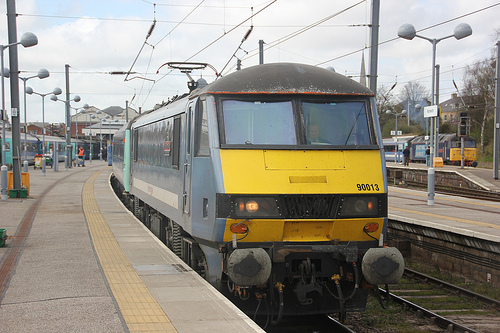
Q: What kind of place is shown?
A: It is a station.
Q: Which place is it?
A: It is a station.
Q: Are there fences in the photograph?
A: No, there are no fences.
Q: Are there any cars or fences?
A: No, there are no fences or cars.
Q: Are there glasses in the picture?
A: No, there are no glasses.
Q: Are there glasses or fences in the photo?
A: No, there are no glasses or fences.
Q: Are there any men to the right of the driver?
A: Yes, there is a man to the right of the driver.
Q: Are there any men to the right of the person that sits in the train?
A: Yes, there is a man to the right of the driver.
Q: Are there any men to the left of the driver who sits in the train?
A: No, the man is to the right of the driver.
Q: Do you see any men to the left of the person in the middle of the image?
A: No, the man is to the right of the driver.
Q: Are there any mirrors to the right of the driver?
A: No, there is a man to the right of the driver.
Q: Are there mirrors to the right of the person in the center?
A: No, there is a man to the right of the driver.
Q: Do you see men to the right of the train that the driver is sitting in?
A: Yes, there is a man to the right of the train.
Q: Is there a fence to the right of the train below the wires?
A: No, there is a man to the right of the train.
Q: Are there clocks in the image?
A: No, there are no clocks.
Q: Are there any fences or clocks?
A: No, there are no clocks or fences.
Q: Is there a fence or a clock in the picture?
A: No, there are no clocks or fences.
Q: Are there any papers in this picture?
A: No, there are no papers.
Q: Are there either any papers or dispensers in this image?
A: No, there are no papers or dispensers.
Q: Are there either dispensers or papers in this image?
A: No, there are no papers or dispensers.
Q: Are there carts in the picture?
A: No, there are no carts.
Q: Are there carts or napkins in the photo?
A: No, there are no carts or napkins.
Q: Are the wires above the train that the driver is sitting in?
A: Yes, the wires are above the train.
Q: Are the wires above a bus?
A: No, the wires are above the train.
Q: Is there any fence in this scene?
A: No, there are no fences.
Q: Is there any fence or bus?
A: No, there are no fences or buses.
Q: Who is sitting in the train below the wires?
A: The driver is sitting in the train.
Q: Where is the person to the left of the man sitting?
A: The driver is sitting in the train.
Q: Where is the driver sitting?
A: The driver is sitting in the train.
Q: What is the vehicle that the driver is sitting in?
A: The vehicle is a train.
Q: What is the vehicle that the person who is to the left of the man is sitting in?
A: The vehicle is a train.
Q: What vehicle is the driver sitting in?
A: The driver is sitting in the train.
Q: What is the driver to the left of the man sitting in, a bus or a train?
A: The driver is sitting in a train.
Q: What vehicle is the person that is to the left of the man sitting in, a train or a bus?
A: The driver is sitting in a train.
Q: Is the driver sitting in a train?
A: Yes, the driver is sitting in a train.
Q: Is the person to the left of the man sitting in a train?
A: Yes, the driver is sitting in a train.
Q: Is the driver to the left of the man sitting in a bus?
A: No, the driver is sitting in a train.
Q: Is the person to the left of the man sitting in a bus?
A: No, the driver is sitting in a train.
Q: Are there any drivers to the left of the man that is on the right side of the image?
A: Yes, there is a driver to the left of the man.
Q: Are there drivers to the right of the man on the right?
A: No, the driver is to the left of the man.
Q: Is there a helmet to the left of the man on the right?
A: No, there is a driver to the left of the man.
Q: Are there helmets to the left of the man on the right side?
A: No, there is a driver to the left of the man.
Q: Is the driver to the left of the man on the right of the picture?
A: Yes, the driver is to the left of the man.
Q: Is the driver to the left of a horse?
A: No, the driver is to the left of the man.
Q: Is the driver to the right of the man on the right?
A: No, the driver is to the left of the man.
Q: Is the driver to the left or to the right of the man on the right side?
A: The driver is to the left of the man.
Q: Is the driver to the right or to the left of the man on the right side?
A: The driver is to the left of the man.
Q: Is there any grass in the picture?
A: Yes, there is grass.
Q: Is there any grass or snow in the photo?
A: Yes, there is grass.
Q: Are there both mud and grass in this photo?
A: No, there is grass but no mud.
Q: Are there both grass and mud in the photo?
A: No, there is grass but no mud.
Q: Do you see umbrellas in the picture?
A: No, there are no umbrellas.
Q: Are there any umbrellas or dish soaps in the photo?
A: No, there are no umbrellas or dish soaps.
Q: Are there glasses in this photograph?
A: No, there are no glasses.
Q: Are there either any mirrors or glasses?
A: No, there are no glasses or mirrors.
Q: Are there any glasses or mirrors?
A: No, there are no glasses or mirrors.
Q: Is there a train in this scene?
A: Yes, there is a train.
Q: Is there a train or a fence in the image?
A: Yes, there is a train.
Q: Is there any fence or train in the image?
A: Yes, there is a train.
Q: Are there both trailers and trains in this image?
A: No, there is a train but no trailers.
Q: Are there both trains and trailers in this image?
A: No, there is a train but no trailers.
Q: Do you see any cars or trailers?
A: No, there are no cars or trailers.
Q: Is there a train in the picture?
A: Yes, there is a train.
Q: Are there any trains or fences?
A: Yes, there is a train.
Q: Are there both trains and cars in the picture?
A: No, there is a train but no cars.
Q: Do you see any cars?
A: No, there are no cars.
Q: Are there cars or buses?
A: No, there are no cars or buses.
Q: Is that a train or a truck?
A: That is a train.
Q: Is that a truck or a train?
A: That is a train.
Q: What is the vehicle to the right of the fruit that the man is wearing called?
A: The vehicle is a train.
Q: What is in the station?
A: The train is in the station.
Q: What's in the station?
A: The train is in the station.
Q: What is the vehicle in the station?
A: The vehicle is a train.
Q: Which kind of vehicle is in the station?
A: The vehicle is a train.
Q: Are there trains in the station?
A: Yes, there is a train in the station.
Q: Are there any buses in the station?
A: No, there is a train in the station.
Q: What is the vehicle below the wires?
A: The vehicle is a train.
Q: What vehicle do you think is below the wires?
A: The vehicle is a train.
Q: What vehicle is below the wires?
A: The vehicle is a train.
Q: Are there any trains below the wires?
A: Yes, there is a train below the wires.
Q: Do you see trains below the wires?
A: Yes, there is a train below the wires.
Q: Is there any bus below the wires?
A: No, there is a train below the wires.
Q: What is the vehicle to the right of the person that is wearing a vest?
A: The vehicle is a train.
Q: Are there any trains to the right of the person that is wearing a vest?
A: Yes, there is a train to the right of the person.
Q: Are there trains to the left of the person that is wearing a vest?
A: No, the train is to the right of the person.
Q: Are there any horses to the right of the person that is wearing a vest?
A: No, there is a train to the right of the person.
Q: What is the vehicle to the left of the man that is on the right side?
A: The vehicle is a train.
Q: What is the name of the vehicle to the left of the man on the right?
A: The vehicle is a train.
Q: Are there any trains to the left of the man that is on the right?
A: Yes, there is a train to the left of the man.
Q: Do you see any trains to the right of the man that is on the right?
A: No, the train is to the left of the man.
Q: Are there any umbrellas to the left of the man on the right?
A: No, there is a train to the left of the man.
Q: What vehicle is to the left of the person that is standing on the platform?
A: The vehicle is a train.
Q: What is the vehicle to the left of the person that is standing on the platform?
A: The vehicle is a train.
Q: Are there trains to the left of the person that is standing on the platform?
A: Yes, there is a train to the left of the person.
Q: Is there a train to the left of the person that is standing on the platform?
A: Yes, there is a train to the left of the person.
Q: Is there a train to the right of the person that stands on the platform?
A: No, the train is to the left of the person.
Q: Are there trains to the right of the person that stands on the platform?
A: No, the train is to the left of the person.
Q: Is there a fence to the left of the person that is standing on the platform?
A: No, there is a train to the left of the person.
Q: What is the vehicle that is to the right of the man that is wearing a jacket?
A: The vehicle is a train.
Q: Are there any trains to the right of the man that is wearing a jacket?
A: Yes, there is a train to the right of the man.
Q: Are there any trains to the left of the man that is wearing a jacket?
A: No, the train is to the right of the man.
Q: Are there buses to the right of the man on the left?
A: No, there is a train to the right of the man.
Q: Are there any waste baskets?
A: No, there are no waste baskets.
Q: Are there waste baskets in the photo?
A: No, there are no waste baskets.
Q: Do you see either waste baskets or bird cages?
A: No, there are no waste baskets or bird cages.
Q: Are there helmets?
A: No, there are no helmets.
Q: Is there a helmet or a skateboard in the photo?
A: No, there are no helmets or skateboards.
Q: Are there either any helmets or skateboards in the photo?
A: No, there are no helmets or skateboards.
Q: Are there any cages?
A: No, there are no cages.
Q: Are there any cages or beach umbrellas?
A: No, there are no cages or beach umbrellas.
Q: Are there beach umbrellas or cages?
A: No, there are no cages or beach umbrellas.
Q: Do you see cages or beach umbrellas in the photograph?
A: No, there are no cages or beach umbrellas.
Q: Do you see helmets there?
A: No, there are no helmets.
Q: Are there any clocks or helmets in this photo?
A: No, there are no helmets or clocks.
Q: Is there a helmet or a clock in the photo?
A: No, there are no helmets or clocks.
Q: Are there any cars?
A: No, there are no cars.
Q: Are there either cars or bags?
A: No, there are no cars or bags.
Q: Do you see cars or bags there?
A: No, there are no cars or bags.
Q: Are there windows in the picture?
A: Yes, there is a window.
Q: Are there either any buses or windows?
A: Yes, there is a window.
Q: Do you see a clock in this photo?
A: No, there are no clocks.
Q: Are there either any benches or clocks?
A: No, there are no clocks or benches.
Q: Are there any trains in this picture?
A: Yes, there is a train.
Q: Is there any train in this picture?
A: Yes, there is a train.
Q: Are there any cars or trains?
A: Yes, there is a train.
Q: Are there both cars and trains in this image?
A: No, there is a train but no cars.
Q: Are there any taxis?
A: No, there are no taxis.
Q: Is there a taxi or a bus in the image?
A: No, there are no taxis or buses.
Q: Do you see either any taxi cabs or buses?
A: No, there are no taxi cabs or buses.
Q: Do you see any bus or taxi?
A: No, there are no taxis or buses.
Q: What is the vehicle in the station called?
A: The vehicle is a train.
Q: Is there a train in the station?
A: Yes, there is a train in the station.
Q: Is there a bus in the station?
A: No, there is a train in the station.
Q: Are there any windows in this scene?
A: Yes, there is a window.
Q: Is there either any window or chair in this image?
A: Yes, there is a window.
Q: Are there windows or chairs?
A: Yes, there is a window.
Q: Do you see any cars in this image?
A: No, there are no cars.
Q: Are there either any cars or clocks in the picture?
A: No, there are no cars or clocks.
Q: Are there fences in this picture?
A: No, there are no fences.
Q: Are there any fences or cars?
A: No, there are no fences or cars.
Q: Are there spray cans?
A: No, there are no spray cans.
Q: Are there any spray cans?
A: No, there are no spray cans.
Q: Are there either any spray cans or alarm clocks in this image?
A: No, there are no spray cans or alarm clocks.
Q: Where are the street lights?
A: The street lights are on the sidewalk.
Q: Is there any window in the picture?
A: Yes, there is a window.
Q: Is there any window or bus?
A: Yes, there is a window.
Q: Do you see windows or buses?
A: Yes, there is a window.